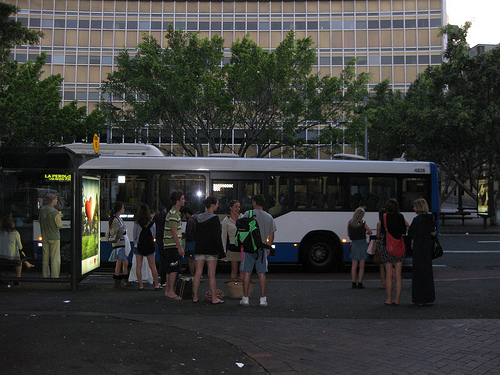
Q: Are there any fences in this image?
A: No, there are no fences.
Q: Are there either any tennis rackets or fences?
A: No, there are no fences or tennis rackets.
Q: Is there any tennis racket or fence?
A: No, there are no fences or rackets.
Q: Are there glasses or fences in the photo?
A: No, there are no fences or glasses.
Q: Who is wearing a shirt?
A: The man is wearing a shirt.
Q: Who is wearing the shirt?
A: The man is wearing a shirt.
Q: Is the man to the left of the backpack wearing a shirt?
A: Yes, the man is wearing a shirt.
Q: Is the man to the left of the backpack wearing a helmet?
A: No, the man is wearing a shirt.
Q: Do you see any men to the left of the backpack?
A: Yes, there is a man to the left of the backpack.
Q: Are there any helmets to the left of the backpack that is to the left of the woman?
A: No, there is a man to the left of the backpack.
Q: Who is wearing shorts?
A: The man is wearing shorts.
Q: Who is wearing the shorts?
A: The man is wearing shorts.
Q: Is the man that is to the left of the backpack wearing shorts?
A: Yes, the man is wearing shorts.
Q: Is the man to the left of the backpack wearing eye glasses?
A: No, the man is wearing shorts.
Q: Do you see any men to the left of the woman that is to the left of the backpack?
A: Yes, there is a man to the left of the woman.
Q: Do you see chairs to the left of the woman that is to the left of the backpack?
A: No, there is a man to the left of the woman.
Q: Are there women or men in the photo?
A: Yes, there is a woman.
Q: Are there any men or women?
A: Yes, there is a woman.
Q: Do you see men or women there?
A: Yes, there is a woman.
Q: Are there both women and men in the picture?
A: Yes, there are both a woman and a man.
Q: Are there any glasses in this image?
A: No, there are no glasses.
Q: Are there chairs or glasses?
A: No, there are no glasses or chairs.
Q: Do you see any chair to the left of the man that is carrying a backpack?
A: No, there is a woman to the left of the man.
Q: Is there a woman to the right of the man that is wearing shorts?
A: Yes, there is a woman to the right of the man.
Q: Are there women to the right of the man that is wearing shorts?
A: Yes, there is a woman to the right of the man.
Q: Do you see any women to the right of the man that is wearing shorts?
A: Yes, there is a woman to the right of the man.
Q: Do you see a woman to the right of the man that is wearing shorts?
A: Yes, there is a woman to the right of the man.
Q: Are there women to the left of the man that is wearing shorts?
A: No, the woman is to the right of the man.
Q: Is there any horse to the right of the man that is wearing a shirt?
A: No, there is a woman to the right of the man.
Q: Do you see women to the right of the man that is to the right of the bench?
A: Yes, there is a woman to the right of the man.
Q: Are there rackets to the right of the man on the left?
A: No, there is a woman to the right of the man.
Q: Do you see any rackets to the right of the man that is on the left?
A: No, there is a woman to the right of the man.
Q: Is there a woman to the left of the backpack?
A: Yes, there is a woman to the left of the backpack.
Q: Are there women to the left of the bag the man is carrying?
A: Yes, there is a woman to the left of the backpack.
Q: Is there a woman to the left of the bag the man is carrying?
A: Yes, there is a woman to the left of the backpack.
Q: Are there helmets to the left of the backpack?
A: No, there is a woman to the left of the backpack.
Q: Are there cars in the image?
A: No, there are no cars.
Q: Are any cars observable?
A: No, there are no cars.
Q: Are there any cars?
A: No, there are no cars.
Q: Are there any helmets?
A: No, there are no helmets.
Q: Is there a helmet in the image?
A: No, there are no helmets.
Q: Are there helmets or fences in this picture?
A: No, there are no helmets or fences.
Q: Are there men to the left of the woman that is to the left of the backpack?
A: Yes, there is a man to the left of the woman.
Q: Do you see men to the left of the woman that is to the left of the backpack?
A: Yes, there is a man to the left of the woman.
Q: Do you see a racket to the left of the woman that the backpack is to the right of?
A: No, there is a man to the left of the woman.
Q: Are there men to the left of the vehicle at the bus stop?
A: Yes, there is a man to the left of the bus.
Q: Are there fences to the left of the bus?
A: No, there is a man to the left of the bus.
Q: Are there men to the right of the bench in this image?
A: Yes, there is a man to the right of the bench.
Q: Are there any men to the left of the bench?
A: No, the man is to the right of the bench.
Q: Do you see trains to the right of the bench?
A: No, there is a man to the right of the bench.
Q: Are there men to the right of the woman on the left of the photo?
A: Yes, there is a man to the right of the woman.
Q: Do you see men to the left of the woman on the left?
A: No, the man is to the right of the woman.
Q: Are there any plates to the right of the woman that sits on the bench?
A: No, there is a man to the right of the woman.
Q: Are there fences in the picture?
A: No, there are no fences.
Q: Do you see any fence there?
A: No, there are no fences.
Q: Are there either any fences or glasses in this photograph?
A: No, there are no fences or glasses.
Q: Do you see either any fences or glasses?
A: No, there are no fences or glasses.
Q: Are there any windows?
A: Yes, there is a window.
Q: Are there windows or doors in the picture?
A: Yes, there is a window.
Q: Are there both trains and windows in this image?
A: No, there is a window but no trains.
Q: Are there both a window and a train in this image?
A: No, there is a window but no trains.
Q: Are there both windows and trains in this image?
A: No, there is a window but no trains.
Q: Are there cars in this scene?
A: No, there are no cars.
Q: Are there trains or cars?
A: No, there are no cars or trains.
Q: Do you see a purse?
A: Yes, there is a purse.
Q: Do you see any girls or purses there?
A: Yes, there is a purse.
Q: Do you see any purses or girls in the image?
A: Yes, there is a purse.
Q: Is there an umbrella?
A: No, there are no umbrellas.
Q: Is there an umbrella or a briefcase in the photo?
A: No, there are no umbrellas or briefcases.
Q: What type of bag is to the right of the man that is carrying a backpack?
A: The bag is a purse.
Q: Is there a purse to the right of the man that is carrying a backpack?
A: Yes, there is a purse to the right of the man.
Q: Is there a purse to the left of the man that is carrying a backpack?
A: No, the purse is to the right of the man.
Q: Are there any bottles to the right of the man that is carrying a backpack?
A: No, there is a purse to the right of the man.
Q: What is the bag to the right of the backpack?
A: The bag is a purse.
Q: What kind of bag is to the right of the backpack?
A: The bag is a purse.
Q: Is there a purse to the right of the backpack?
A: Yes, there is a purse to the right of the backpack.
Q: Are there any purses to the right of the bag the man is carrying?
A: Yes, there is a purse to the right of the backpack.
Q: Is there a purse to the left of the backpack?
A: No, the purse is to the right of the backpack.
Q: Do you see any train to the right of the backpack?
A: No, there is a purse to the right of the backpack.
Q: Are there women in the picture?
A: Yes, there is a woman.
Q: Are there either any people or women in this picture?
A: Yes, there is a woman.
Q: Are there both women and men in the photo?
A: Yes, there are both a woman and men.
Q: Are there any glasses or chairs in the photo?
A: No, there are no glasses or chairs.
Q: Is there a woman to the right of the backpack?
A: Yes, there is a woman to the right of the backpack.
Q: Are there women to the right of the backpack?
A: Yes, there is a woman to the right of the backpack.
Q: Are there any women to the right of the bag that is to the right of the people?
A: Yes, there is a woman to the right of the backpack.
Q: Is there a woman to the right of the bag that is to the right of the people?
A: Yes, there is a woman to the right of the backpack.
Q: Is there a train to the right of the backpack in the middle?
A: No, there is a woman to the right of the backpack.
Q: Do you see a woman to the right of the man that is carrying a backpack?
A: Yes, there is a woman to the right of the man.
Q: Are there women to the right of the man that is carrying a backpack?
A: Yes, there is a woman to the right of the man.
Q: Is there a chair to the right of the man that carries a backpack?
A: No, there is a woman to the right of the man.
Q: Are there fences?
A: No, there are no fences.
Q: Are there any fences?
A: No, there are no fences.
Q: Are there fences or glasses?
A: No, there are no fences or glasses.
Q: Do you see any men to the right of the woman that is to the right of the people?
A: Yes, there is a man to the right of the woman.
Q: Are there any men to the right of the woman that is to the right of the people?
A: Yes, there is a man to the right of the woman.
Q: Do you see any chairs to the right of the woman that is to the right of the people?
A: No, there is a man to the right of the woman.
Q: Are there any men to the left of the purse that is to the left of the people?
A: Yes, there is a man to the left of the purse.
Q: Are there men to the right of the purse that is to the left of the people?
A: No, the man is to the left of the purse.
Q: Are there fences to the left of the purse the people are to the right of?
A: No, there is a man to the left of the purse.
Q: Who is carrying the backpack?
A: The man is carrying the backpack.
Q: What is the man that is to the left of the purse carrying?
A: The man is carrying a backpack.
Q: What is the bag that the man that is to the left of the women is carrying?
A: The bag is a backpack.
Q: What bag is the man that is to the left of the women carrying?
A: The man is carrying a backpack.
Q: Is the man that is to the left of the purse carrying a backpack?
A: Yes, the man is carrying a backpack.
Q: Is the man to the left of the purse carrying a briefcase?
A: No, the man is carrying a backpack.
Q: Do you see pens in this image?
A: No, there are no pens.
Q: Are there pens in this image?
A: No, there are no pens.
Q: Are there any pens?
A: No, there are no pens.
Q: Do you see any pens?
A: No, there are no pens.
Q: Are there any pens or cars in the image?
A: No, there are no pens or cars.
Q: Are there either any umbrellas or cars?
A: No, there are no cars or umbrellas.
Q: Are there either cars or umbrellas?
A: No, there are no cars or umbrellas.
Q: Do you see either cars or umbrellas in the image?
A: No, there are no cars or umbrellas.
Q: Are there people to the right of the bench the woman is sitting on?
A: Yes, there are people to the right of the bench.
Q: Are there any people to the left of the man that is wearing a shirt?
A: Yes, there are people to the left of the man.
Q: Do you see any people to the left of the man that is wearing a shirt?
A: Yes, there are people to the left of the man.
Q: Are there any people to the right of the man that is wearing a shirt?
A: No, the people are to the left of the man.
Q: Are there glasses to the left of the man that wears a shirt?
A: No, there are people to the left of the man.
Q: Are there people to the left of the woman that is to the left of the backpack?
A: Yes, there are people to the left of the woman.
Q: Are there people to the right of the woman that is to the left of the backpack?
A: No, the people are to the left of the woman.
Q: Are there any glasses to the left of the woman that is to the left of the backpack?
A: No, there are people to the left of the woman.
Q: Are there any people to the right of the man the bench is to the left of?
A: Yes, there are people to the right of the man.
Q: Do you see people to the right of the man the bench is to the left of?
A: Yes, there are people to the right of the man.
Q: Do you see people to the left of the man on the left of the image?
A: No, the people are to the right of the man.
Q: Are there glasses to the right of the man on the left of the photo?
A: No, there are people to the right of the man.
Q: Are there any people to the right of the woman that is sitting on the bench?
A: Yes, there are people to the right of the woman.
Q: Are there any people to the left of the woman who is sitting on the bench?
A: No, the people are to the right of the woman.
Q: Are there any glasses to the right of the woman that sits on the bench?
A: No, there are people to the right of the woman.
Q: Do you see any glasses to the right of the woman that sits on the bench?
A: No, there are people to the right of the woman.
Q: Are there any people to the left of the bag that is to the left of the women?
A: Yes, there are people to the left of the backpack.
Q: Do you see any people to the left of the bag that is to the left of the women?
A: Yes, there are people to the left of the backpack.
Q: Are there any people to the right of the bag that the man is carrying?
A: No, the people are to the left of the backpack.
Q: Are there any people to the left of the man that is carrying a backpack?
A: Yes, there are people to the left of the man.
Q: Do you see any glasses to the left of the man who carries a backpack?
A: No, there are people to the left of the man.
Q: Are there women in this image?
A: Yes, there are women.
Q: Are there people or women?
A: Yes, there are women.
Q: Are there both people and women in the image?
A: Yes, there are both women and a person.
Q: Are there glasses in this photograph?
A: No, there are no glasses.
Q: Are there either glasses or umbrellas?
A: No, there are no glasses or umbrellas.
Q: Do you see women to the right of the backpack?
A: Yes, there are women to the right of the backpack.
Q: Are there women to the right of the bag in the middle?
A: Yes, there are women to the right of the backpack.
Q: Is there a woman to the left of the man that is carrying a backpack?
A: No, the women are to the right of the man.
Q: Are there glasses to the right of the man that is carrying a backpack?
A: No, there are women to the right of the man.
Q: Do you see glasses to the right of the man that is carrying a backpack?
A: No, there are women to the right of the man.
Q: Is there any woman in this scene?
A: Yes, there are women.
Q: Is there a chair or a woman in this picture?
A: Yes, there are women.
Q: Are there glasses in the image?
A: No, there are no glasses.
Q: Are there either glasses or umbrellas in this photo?
A: No, there are no glasses or umbrellas.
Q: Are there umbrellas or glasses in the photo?
A: No, there are no glasses or umbrellas.